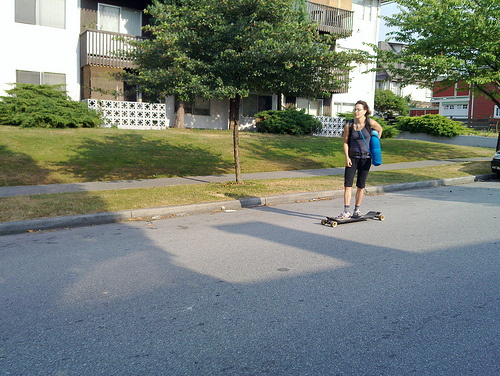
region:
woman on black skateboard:
[318, 98, 388, 231]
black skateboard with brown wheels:
[313, 205, 388, 230]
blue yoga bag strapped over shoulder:
[316, 97, 388, 229]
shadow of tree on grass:
[48, 128, 243, 182]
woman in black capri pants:
[316, 100, 388, 228]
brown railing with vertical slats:
[82, 28, 163, 71]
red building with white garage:
[408, 63, 498, 123]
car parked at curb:
[485, 122, 499, 178]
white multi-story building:
[0, 0, 377, 148]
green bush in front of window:
[1, 85, 104, 127]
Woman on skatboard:
[299, 90, 386, 232]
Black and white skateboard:
[313, 198, 388, 238]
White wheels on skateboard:
[319, 208, 386, 232]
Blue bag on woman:
[341, 109, 388, 171]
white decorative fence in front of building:
[80, 78, 181, 141]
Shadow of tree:
[47, 121, 240, 183]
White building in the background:
[2, 0, 442, 148]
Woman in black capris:
[337, 139, 374, 194]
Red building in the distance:
[388, 43, 498, 141]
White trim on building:
[400, 74, 474, 128]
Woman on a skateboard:
[320, 99, 392, 226]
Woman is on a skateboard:
[315, 95, 387, 230]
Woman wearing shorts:
[342, 151, 372, 187]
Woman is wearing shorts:
[340, 153, 370, 188]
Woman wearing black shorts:
[340, 153, 373, 190]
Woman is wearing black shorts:
[340, 155, 374, 190]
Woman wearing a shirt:
[344, 114, 374, 159]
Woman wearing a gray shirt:
[344, 113, 373, 158]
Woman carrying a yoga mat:
[354, 117, 386, 167]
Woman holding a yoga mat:
[350, 113, 386, 167]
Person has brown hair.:
[353, 90, 375, 127]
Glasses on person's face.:
[343, 101, 365, 115]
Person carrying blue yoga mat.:
[354, 128, 408, 175]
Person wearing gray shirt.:
[345, 130, 372, 162]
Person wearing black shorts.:
[337, 154, 375, 178]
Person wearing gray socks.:
[340, 200, 365, 212]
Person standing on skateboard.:
[335, 209, 373, 225]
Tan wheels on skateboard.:
[326, 205, 394, 243]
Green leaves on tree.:
[203, 40, 265, 78]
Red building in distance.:
[449, 78, 491, 115]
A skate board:
[342, 219, 365, 221]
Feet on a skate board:
[341, 214, 361, 216]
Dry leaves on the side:
[313, 199, 326, 201]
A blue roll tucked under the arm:
[373, 137, 378, 160]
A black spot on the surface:
[281, 269, 285, 271]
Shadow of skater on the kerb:
[248, 200, 258, 204]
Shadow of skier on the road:
[273, 207, 279, 211]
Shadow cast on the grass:
[51, 200, 83, 209]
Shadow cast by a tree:
[123, 150, 170, 165]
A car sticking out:
[493, 157, 499, 167]